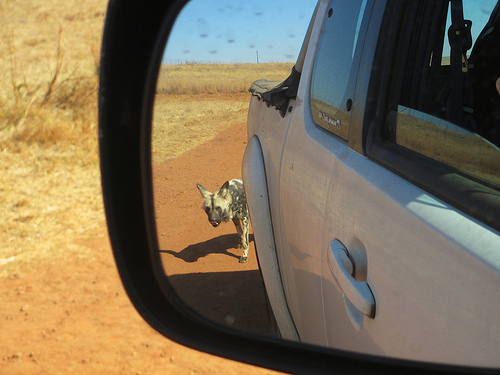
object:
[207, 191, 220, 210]
line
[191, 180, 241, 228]
head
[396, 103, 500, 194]
window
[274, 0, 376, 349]
door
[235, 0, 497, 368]
car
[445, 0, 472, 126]
seatbelt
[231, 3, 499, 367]
car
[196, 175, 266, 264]
hyena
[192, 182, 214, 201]
ears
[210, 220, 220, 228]
nose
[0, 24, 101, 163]
plant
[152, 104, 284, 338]
road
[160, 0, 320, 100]
water mark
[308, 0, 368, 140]
side window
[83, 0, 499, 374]
trim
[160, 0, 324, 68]
sky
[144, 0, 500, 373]
mirror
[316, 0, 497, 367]
door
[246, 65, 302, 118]
cover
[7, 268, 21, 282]
rock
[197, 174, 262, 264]
dog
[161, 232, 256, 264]
shadow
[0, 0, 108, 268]
grass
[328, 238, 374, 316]
handle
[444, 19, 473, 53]
buckle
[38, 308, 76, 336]
trail